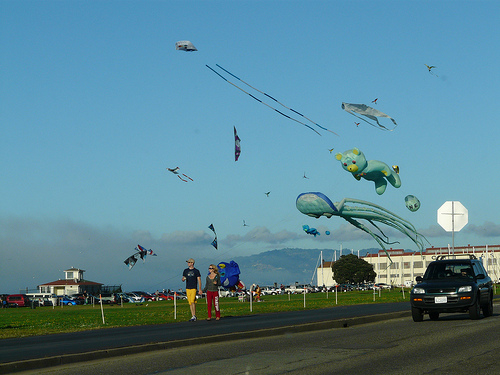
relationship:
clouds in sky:
[0, 213, 499, 293] [2, 0, 496, 292]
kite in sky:
[330, 90, 459, 176] [24, 20, 489, 324]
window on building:
[375, 262, 388, 270] [313, 251, 498, 289]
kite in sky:
[334, 145, 408, 196] [103, 31, 449, 290]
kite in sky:
[174, 40, 340, 137] [103, 31, 449, 290]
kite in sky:
[224, 122, 245, 166] [103, 31, 449, 290]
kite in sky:
[201, 218, 222, 255] [103, 31, 449, 290]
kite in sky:
[341, 102, 398, 132] [103, 31, 449, 290]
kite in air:
[231, 161, 418, 253] [245, 174, 448, 265]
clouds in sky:
[65, 183, 140, 234] [2, 3, 482, 246]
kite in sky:
[133, 33, 328, 133] [2, 3, 482, 246]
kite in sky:
[111, 215, 166, 270] [2, 3, 482, 246]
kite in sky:
[231, 123, 242, 160] [2, 3, 482, 246]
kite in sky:
[170, 33, 201, 67] [2, 3, 482, 246]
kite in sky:
[333, 98, 400, 133] [2, 0, 496, 292]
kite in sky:
[327, 137, 415, 189] [2, 4, 484, 211]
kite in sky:
[294, 192, 432, 272] [406, 121, 475, 177]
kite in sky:
[301, 222, 319, 235] [2, 3, 482, 246]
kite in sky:
[338, 96, 400, 137] [2, 0, 496, 292]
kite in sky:
[419, 60, 438, 78] [2, 3, 482, 246]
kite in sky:
[127, 10, 433, 260] [236, 30, 376, 67]